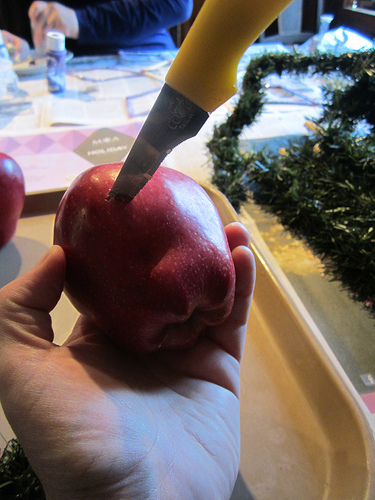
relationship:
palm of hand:
[69, 340, 230, 464] [0, 219, 257, 497]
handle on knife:
[164, 2, 296, 112] [113, 0, 296, 200]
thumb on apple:
[0, 244, 64, 395] [52, 162, 234, 350]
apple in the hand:
[53, 161, 237, 352] [0, 221, 256, 500]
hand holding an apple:
[1, 212, 287, 485] [53, 161, 237, 352]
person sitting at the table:
[18, 0, 195, 55] [0, 26, 374, 199]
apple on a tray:
[4, 147, 23, 252] [22, 187, 49, 242]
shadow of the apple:
[0, 236, 48, 288] [0, 153, 24, 251]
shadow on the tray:
[0, 236, 48, 288] [9, 174, 372, 499]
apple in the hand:
[53, 161, 237, 352] [4, 331, 258, 480]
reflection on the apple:
[166, 172, 227, 253] [50, 157, 246, 352]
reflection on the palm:
[156, 422, 206, 467] [141, 421, 206, 464]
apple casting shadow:
[50, 157, 246, 352] [74, 332, 190, 394]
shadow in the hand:
[74, 332, 190, 394] [1, 212, 287, 485]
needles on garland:
[215, 55, 373, 314] [208, 42, 367, 314]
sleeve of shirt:
[65, 2, 193, 52] [73, 2, 192, 42]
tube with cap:
[44, 32, 68, 94] [45, 30, 64, 51]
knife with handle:
[113, 0, 296, 200] [164, 2, 296, 112]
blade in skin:
[101, 108, 210, 203] [99, 205, 126, 214]